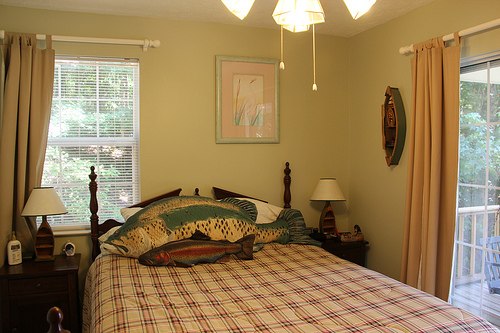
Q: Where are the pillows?
A: Bed.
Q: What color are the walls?
A: Cream.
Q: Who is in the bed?
A: No one.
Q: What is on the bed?
A: Fish.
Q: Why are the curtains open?
A: For light.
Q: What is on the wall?
A: Picture.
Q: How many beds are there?
A: One.